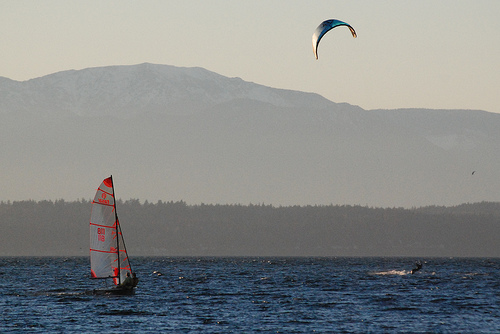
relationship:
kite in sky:
[313, 19, 357, 61] [2, 2, 312, 62]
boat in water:
[94, 275, 141, 298] [1, 295, 499, 333]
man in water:
[411, 262, 425, 274] [1, 295, 499, 333]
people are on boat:
[122, 272, 139, 288] [94, 275, 141, 298]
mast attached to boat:
[116, 230, 123, 285] [94, 275, 141, 298]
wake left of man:
[372, 266, 408, 280] [411, 262, 425, 274]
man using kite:
[411, 262, 425, 274] [313, 19, 357, 61]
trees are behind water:
[128, 194, 499, 258] [1, 295, 499, 333]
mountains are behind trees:
[0, 63, 499, 133] [128, 194, 499, 258]